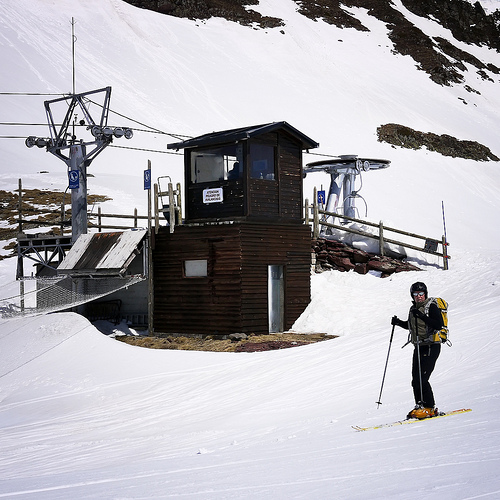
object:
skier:
[389, 280, 451, 421]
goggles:
[411, 291, 426, 298]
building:
[150, 122, 311, 332]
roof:
[168, 121, 319, 152]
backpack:
[429, 297, 450, 346]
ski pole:
[373, 314, 397, 410]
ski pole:
[413, 313, 425, 411]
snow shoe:
[413, 407, 441, 420]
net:
[0, 270, 145, 323]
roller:
[92, 124, 104, 138]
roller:
[102, 126, 114, 140]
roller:
[114, 126, 123, 139]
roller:
[124, 127, 134, 139]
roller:
[25, 137, 35, 148]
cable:
[0, 133, 186, 158]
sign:
[201, 188, 226, 204]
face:
[412, 291, 426, 304]